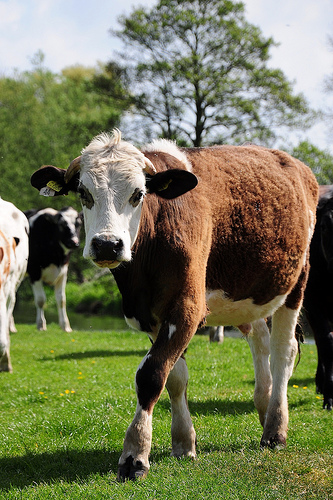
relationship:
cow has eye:
[16, 114, 331, 485] [129, 185, 147, 206]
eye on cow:
[72, 180, 97, 209] [16, 114, 331, 485]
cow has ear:
[16, 114, 331, 485] [145, 161, 200, 202]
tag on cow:
[39, 180, 57, 195] [16, 114, 331, 485]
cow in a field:
[16, 114, 331, 485] [5, 307, 329, 497]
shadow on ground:
[3, 433, 116, 491] [5, 307, 329, 497]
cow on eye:
[16, 114, 331, 485] [129, 185, 147, 206]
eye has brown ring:
[129, 185, 147, 206] [126, 184, 149, 212]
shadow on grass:
[3, 433, 116, 491] [5, 307, 329, 497]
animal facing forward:
[16, 114, 331, 485] [3, 0, 325, 500]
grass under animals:
[5, 307, 329, 497] [16, 114, 331, 485]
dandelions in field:
[247, 440, 328, 495] [5, 307, 329, 497]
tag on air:
[32, 185, 58, 203] [23, 161, 78, 202]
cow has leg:
[16, 114, 331, 485] [114, 312, 197, 486]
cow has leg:
[16, 114, 331, 485] [165, 360, 202, 466]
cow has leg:
[16, 114, 331, 485] [264, 311, 301, 450]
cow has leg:
[16, 114, 331, 485] [244, 318, 273, 438]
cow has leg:
[23, 199, 85, 335] [52, 282, 73, 336]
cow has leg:
[23, 199, 85, 335] [28, 280, 50, 335]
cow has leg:
[0, 207, 36, 371] [0, 298, 15, 370]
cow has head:
[16, 114, 331, 485] [23, 123, 205, 288]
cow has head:
[23, 199, 85, 335] [50, 199, 86, 260]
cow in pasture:
[16, 114, 331, 485] [5, 307, 329, 497]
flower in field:
[54, 384, 79, 401] [5, 307, 329, 497]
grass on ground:
[5, 307, 329, 497] [30, 387, 114, 464]